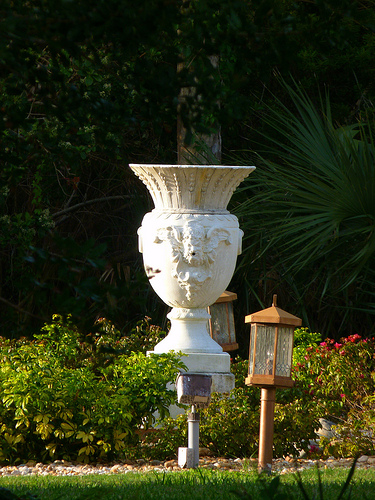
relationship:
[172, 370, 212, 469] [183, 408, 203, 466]
light on metal stand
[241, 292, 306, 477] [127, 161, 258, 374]
brown accessory in front of urn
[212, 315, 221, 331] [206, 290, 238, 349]
lightbulb inside bronze light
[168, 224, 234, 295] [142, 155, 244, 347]
face of statue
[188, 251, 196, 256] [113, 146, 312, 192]
hole in mouth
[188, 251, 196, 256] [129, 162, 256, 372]
hole of statue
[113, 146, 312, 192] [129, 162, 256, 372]
mouth of statue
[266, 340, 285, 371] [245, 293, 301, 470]
bulb inside light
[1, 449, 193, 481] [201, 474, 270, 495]
gravel behind grass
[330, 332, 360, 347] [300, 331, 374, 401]
flowers on bush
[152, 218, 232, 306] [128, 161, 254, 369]
carving on stone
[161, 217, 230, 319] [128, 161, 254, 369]
carving on stone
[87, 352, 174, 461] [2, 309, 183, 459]
bush in a group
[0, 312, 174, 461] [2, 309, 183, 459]
bush in a group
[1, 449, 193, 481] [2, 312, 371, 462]
gravel underneath bushes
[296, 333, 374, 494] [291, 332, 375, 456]
bush has flowers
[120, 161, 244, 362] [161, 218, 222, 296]
vase has pattern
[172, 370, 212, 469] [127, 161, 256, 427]
light pointed towards vase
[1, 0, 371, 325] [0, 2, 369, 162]
tree are in forest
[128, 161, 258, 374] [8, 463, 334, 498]
sculture around grass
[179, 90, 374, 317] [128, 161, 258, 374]
palm tree behind sculture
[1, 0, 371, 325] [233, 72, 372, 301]
tree behind tree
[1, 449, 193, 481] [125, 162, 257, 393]
gravel around statue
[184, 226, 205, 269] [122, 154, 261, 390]
sculture on urn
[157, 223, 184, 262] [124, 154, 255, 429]
wing on urn